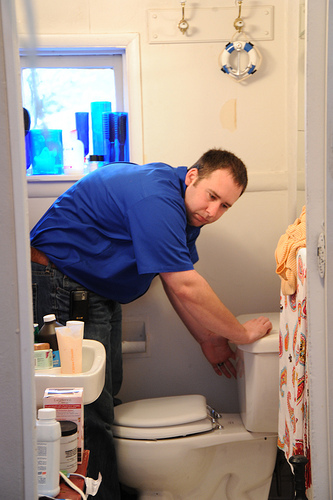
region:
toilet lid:
[139, 401, 177, 412]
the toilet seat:
[140, 428, 159, 436]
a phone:
[73, 288, 90, 309]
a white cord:
[72, 481, 84, 494]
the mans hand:
[202, 336, 237, 368]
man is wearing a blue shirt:
[84, 205, 125, 248]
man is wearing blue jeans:
[40, 280, 62, 312]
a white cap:
[42, 311, 57, 321]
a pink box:
[46, 391, 82, 410]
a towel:
[285, 331, 304, 451]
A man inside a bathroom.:
[31, 147, 271, 499]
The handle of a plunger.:
[288, 453, 308, 499]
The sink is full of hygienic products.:
[33, 313, 105, 406]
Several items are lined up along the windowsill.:
[20, 34, 143, 197]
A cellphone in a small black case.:
[68, 287, 89, 323]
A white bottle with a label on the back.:
[34, 408, 61, 496]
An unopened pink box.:
[41, 387, 83, 462]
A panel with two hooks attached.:
[147, 0, 274, 44]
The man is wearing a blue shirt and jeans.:
[32, 147, 273, 499]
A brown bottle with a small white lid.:
[39, 313, 65, 366]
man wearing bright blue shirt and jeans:
[30, 146, 274, 498]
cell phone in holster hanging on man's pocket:
[67, 287, 92, 323]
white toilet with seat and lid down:
[112, 310, 282, 498]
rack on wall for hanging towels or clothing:
[145, 0, 275, 43]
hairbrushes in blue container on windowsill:
[101, 111, 130, 163]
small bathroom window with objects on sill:
[15, 32, 142, 198]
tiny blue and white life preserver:
[219, 31, 263, 80]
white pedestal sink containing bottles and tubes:
[33, 337, 107, 406]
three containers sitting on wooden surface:
[34, 385, 89, 498]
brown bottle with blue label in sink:
[36, 312, 66, 365]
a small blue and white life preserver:
[218, 31, 262, 82]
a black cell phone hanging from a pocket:
[69, 288, 89, 320]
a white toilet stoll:
[113, 312, 296, 498]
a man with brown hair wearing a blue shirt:
[29, 149, 271, 499]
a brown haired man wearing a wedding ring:
[30, 148, 272, 499]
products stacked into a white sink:
[31, 311, 103, 407]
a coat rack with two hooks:
[144, 1, 275, 42]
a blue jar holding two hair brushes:
[102, 112, 129, 162]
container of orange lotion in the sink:
[54, 324, 83, 373]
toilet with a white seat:
[115, 311, 280, 498]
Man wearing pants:
[26, 263, 136, 498]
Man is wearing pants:
[26, 259, 130, 498]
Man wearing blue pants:
[28, 260, 128, 498]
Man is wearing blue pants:
[27, 259, 128, 497]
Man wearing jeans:
[26, 260, 129, 498]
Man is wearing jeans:
[27, 261, 127, 499]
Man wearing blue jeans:
[28, 259, 127, 497]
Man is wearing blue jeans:
[29, 260, 131, 498]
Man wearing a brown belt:
[25, 242, 66, 271]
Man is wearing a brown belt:
[28, 241, 67, 270]